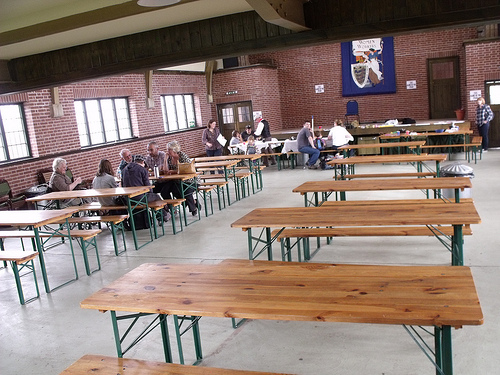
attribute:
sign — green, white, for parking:
[341, 36, 396, 96]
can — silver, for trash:
[440, 163, 473, 199]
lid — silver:
[436, 163, 473, 176]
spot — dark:
[278, 350, 316, 365]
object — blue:
[344, 32, 398, 97]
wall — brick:
[248, 22, 483, 131]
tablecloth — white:
[233, 135, 313, 152]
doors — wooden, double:
[213, 97, 260, 151]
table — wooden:
[81, 260, 483, 373]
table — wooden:
[236, 198, 479, 263]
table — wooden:
[296, 177, 471, 197]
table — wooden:
[328, 152, 443, 173]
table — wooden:
[5, 207, 84, 292]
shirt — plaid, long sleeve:
[461, 92, 496, 144]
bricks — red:
[287, 57, 300, 82]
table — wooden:
[5, 128, 483, 373]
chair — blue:
[316, 135, 473, 187]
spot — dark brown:
[294, 281, 308, 291]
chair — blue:
[344, 98, 361, 125]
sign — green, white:
[326, 39, 430, 120]